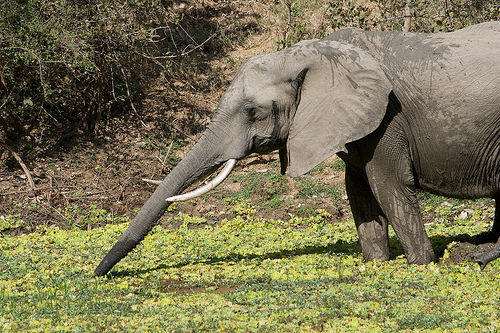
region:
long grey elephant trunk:
[94, 129, 237, 286]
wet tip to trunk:
[63, 230, 145, 295]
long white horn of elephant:
[161, 159, 243, 220]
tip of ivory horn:
[126, 177, 159, 197]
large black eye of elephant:
[248, 103, 254, 110]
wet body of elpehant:
[335, 109, 482, 251]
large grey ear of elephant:
[270, 34, 378, 176]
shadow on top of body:
[392, 36, 464, 71]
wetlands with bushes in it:
[32, 260, 197, 322]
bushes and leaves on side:
[8, 8, 118, 120]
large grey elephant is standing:
[93, 19, 498, 274]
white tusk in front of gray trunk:
[162, 158, 243, 201]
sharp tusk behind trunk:
[141, 176, 159, 186]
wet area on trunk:
[91, 238, 140, 272]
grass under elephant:
[0, 220, 499, 331]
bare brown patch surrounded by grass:
[163, 281, 231, 294]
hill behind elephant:
[1, 0, 496, 212]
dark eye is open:
[246, 103, 254, 110]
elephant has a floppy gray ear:
[284, 36, 394, 178]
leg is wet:
[362, 124, 439, 259]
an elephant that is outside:
[84, 23, 486, 275]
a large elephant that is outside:
[57, 12, 448, 323]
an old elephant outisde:
[108, 28, 494, 294]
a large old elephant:
[39, 34, 497, 304]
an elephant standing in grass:
[99, 47, 481, 258]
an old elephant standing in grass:
[116, 45, 481, 267]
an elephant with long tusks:
[144, 48, 493, 301]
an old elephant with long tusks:
[110, 21, 449, 218]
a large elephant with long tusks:
[82, 44, 499, 187]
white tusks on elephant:
[132, 140, 239, 209]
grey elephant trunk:
[85, 125, 217, 293]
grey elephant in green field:
[74, 18, 499, 282]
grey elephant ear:
[284, 31, 397, 186]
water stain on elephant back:
[283, 33, 473, 103]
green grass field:
[1, 203, 493, 329]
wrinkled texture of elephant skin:
[390, 118, 425, 181]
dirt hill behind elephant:
[2, 0, 498, 232]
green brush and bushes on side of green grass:
[1, 2, 210, 167]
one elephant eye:
[232, 98, 269, 123]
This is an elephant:
[74, 17, 498, 280]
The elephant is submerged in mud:
[321, 213, 498, 277]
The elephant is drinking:
[69, 228, 149, 285]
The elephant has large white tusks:
[132, 144, 252, 206]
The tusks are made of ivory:
[113, 154, 272, 201]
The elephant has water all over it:
[317, 29, 477, 246]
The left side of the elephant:
[187, 31, 499, 264]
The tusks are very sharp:
[135, 136, 248, 218]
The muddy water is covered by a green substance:
[26, 235, 436, 329]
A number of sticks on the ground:
[5, 148, 129, 210]